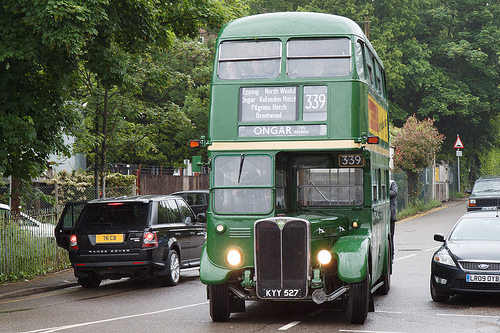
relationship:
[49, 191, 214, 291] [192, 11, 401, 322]
car to left of bus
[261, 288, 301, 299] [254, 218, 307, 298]
plate on grill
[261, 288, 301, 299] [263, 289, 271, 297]
plate has letter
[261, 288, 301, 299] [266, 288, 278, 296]
plate has letter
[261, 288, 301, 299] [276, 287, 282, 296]
plate has letter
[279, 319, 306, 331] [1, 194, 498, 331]
white line painted on pavement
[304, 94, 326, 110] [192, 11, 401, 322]
numbers 339 on bus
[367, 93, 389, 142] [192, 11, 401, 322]
yellow sign painted on bus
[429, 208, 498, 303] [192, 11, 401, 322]
car is black to right of bus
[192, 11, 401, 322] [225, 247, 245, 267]
bus has headlight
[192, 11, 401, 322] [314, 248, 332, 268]
bus has headlight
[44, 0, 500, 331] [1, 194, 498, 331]
traffic on a street on a pavement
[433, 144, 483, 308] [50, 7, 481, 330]
vehicles in traffic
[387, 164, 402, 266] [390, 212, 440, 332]
person standing in street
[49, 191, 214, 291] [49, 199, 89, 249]
car with door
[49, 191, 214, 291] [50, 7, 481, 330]
car in traffic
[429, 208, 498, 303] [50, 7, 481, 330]
car is black in traffic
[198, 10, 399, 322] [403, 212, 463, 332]
bus on street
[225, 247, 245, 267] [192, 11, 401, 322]
headlight on a bus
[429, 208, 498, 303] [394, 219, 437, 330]
car is black parked on street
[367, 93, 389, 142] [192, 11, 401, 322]
yellow sign on side of bus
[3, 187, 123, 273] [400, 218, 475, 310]
metal fence on side of street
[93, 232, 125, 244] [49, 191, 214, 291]
plate for car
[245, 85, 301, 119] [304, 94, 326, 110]
letters with numbers 339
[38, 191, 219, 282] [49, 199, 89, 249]
car with door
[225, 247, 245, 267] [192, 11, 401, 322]
headlight on bus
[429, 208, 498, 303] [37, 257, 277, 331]
car is black on side of road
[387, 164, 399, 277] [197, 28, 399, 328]
person hanging on bus